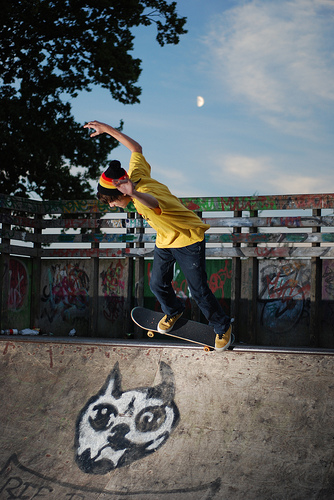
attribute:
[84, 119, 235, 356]
boy — skateboaring, balancing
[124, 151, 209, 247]
shirt — yellow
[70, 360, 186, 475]
dog — painted, white, black, graffiti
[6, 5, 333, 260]
sky — blue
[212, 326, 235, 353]
tennis shoe — yellow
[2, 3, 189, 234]
tree — outlined, in sky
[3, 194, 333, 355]
fence — spray painted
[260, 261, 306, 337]
number 5 — painted, graffiti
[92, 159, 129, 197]
hat — yellow, white, orange, striped, knit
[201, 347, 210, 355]
wheel — yellow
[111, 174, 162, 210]
arm — up high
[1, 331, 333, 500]
ramp — concrete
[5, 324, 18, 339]
trash — on its side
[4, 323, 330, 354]
platform — skating surface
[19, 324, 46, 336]
trash — empty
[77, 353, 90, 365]
mark — black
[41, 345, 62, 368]
mark — scraped paint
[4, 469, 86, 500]
writing — black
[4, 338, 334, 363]
band — metal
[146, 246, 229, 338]
jeans — blue